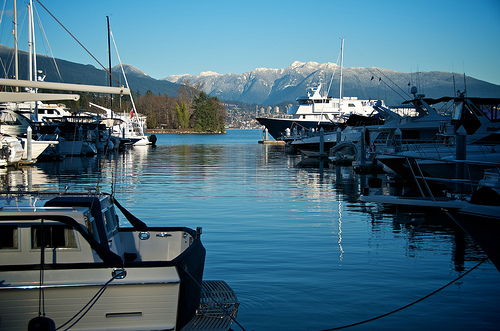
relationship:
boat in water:
[411, 147, 498, 205] [1, 127, 498, 329]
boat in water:
[251, 93, 388, 144] [1, 127, 498, 329]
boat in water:
[374, 148, 425, 188] [1, 127, 498, 329]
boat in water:
[0, 187, 241, 330] [1, 127, 498, 329]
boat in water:
[107, 104, 158, 151] [1, 127, 498, 329]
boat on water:
[0, 187, 241, 330] [1, 127, 498, 329]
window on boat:
[377, 127, 432, 147] [314, 112, 496, 151]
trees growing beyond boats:
[185, 98, 222, 133] [256, 74, 423, 147]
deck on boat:
[189, 276, 240, 328] [1, 165, 243, 323]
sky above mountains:
[0, 0, 495, 98] [144, 50, 499, 137]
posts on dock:
[317, 126, 327, 161] [343, 128, 498, 188]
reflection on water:
[284, 160, 339, 213] [28, 133, 495, 325]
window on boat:
[0, 226, 23, 249] [0, 99, 144, 145]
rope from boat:
[183, 262, 246, 329] [0, 187, 241, 330]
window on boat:
[33, 227, 71, 245] [3, 197, 198, 326]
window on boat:
[319, 97, 329, 102] [246, 92, 406, 150]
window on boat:
[0, 226, 23, 249] [254, 95, 443, 142]